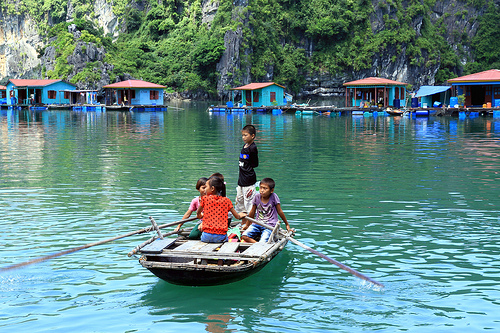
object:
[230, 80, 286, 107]
hut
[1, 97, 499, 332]
river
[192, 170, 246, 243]
children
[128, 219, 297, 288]
boat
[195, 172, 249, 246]
girl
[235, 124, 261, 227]
boy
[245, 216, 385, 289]
an oar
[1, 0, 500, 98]
mountain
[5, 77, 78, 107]
hut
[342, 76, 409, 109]
hut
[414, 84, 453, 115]
hut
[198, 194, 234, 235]
blouse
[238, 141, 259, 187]
t-shirt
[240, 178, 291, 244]
boy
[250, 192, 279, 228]
shirt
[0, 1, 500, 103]
vegetation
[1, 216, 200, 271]
oar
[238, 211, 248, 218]
hand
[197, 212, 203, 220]
hand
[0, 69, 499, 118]
community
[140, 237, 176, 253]
board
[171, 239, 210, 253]
board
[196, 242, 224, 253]
board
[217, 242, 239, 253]
board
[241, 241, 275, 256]
board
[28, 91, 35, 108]
person